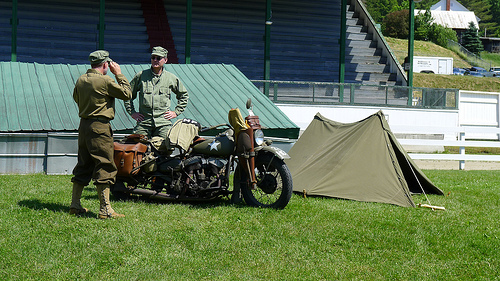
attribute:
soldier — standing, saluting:
[69, 49, 134, 220]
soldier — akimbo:
[123, 43, 189, 139]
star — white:
[207, 139, 219, 151]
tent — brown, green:
[275, 108, 445, 211]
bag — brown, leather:
[112, 140, 150, 179]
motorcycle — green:
[106, 97, 292, 212]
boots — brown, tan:
[69, 180, 125, 220]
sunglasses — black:
[150, 55, 165, 61]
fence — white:
[389, 124, 500, 169]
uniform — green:
[125, 67, 188, 140]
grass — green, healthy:
[1, 167, 499, 280]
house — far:
[413, 8, 481, 48]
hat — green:
[150, 45, 169, 59]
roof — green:
[1, 61, 299, 134]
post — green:
[11, 1, 19, 61]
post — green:
[99, 1, 107, 49]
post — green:
[184, 1, 193, 63]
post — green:
[262, 0, 272, 100]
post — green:
[336, 1, 348, 102]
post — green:
[407, 1, 415, 105]